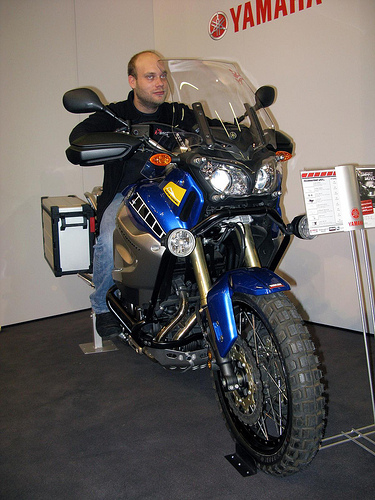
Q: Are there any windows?
A: Yes, there is a window.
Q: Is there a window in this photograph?
A: Yes, there is a window.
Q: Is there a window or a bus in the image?
A: Yes, there is a window.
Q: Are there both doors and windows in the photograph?
A: No, there is a window but no doors.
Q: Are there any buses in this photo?
A: No, there are no buses.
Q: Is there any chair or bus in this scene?
A: No, there are no buses or chairs.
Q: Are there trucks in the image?
A: No, there are no trucks.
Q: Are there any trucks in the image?
A: No, there are no trucks.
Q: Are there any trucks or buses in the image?
A: No, there are no trucks or buses.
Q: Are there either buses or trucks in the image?
A: No, there are no trucks or buses.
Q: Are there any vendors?
A: No, there are no vendors.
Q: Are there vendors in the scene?
A: No, there are no vendors.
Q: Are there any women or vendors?
A: No, there are no vendors or women.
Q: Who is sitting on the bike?
A: The man is sitting on the bike.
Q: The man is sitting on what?
A: The man is sitting on the bike.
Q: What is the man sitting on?
A: The man is sitting on the bike.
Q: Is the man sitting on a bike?
A: Yes, the man is sitting on a bike.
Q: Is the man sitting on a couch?
A: No, the man is sitting on a bike.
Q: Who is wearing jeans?
A: The man is wearing jeans.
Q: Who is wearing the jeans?
A: The man is wearing jeans.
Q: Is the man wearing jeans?
A: Yes, the man is wearing jeans.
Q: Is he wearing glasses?
A: No, the man is wearing jeans.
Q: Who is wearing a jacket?
A: The man is wearing a jacket.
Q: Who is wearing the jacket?
A: The man is wearing a jacket.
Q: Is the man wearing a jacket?
A: Yes, the man is wearing a jacket.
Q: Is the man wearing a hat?
A: No, the man is wearing a jacket.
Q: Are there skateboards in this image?
A: No, there are no skateboards.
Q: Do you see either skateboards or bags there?
A: No, there are no skateboards or bags.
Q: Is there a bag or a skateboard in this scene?
A: No, there are no skateboards or bags.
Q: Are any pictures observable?
A: No, there are no pictures.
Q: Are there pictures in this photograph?
A: No, there are no pictures.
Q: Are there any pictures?
A: No, there are no pictures.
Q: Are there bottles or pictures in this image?
A: No, there are no pictures or bottles.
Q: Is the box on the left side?
A: Yes, the box is on the left of the image.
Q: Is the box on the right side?
A: No, the box is on the left of the image.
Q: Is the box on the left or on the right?
A: The box is on the left of the image.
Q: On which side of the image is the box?
A: The box is on the left of the image.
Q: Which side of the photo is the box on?
A: The box is on the left of the image.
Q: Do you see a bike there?
A: Yes, there is a bike.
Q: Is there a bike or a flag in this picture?
A: Yes, there is a bike.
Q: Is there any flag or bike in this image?
A: Yes, there is a bike.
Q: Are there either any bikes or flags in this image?
A: Yes, there is a bike.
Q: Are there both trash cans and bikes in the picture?
A: No, there is a bike but no trash cans.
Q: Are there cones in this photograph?
A: No, there are no cones.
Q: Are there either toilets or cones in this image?
A: No, there are no cones or toilets.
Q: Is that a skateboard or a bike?
A: That is a bike.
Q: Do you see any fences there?
A: No, there are no fences.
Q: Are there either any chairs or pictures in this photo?
A: No, there are no pictures or chairs.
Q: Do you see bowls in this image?
A: No, there are no bowls.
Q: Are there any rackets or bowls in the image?
A: No, there are no bowls or rackets.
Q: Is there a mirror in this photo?
A: Yes, there is a mirror.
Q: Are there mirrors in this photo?
A: Yes, there is a mirror.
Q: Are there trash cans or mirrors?
A: Yes, there is a mirror.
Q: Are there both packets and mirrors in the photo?
A: No, there is a mirror but no packets.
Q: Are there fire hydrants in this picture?
A: No, there are no fire hydrants.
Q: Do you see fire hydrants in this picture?
A: No, there are no fire hydrants.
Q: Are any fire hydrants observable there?
A: No, there are no fire hydrants.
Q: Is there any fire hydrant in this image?
A: No, there are no fire hydrants.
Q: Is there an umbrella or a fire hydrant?
A: No, there are no fire hydrants or umbrellas.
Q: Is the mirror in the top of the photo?
A: Yes, the mirror is in the top of the image.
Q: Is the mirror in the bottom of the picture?
A: No, the mirror is in the top of the image.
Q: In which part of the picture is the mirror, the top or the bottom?
A: The mirror is in the top of the image.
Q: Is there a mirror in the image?
A: Yes, there is a mirror.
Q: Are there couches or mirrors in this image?
A: Yes, there is a mirror.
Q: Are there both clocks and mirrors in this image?
A: No, there is a mirror but no clocks.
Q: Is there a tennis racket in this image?
A: No, there are no rackets.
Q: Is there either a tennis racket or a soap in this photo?
A: No, there are no rackets or soaps.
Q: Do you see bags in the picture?
A: No, there are no bags.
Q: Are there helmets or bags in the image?
A: No, there are no bags or helmets.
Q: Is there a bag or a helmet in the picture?
A: No, there are no bags or helmets.